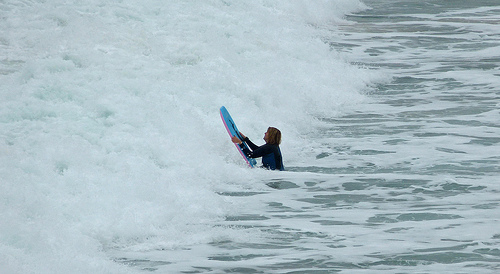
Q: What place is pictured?
A: It is a beach.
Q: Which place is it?
A: It is a beach.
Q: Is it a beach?
A: Yes, it is a beach.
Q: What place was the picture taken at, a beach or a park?
A: It was taken at a beach.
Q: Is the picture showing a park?
A: No, the picture is showing a beach.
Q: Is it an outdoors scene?
A: Yes, it is outdoors.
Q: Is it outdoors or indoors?
A: It is outdoors.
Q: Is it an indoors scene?
A: No, it is outdoors.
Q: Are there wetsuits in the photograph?
A: Yes, there is a wetsuit.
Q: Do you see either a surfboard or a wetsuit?
A: Yes, there is a wetsuit.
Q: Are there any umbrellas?
A: No, there are no umbrellas.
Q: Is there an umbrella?
A: No, there are no umbrellas.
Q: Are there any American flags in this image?
A: No, there are no American flags.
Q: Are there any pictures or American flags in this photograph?
A: No, there are no American flags or pictures.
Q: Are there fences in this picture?
A: No, there are no fences.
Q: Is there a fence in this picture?
A: No, there are no fences.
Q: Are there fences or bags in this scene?
A: No, there are no fences or bags.